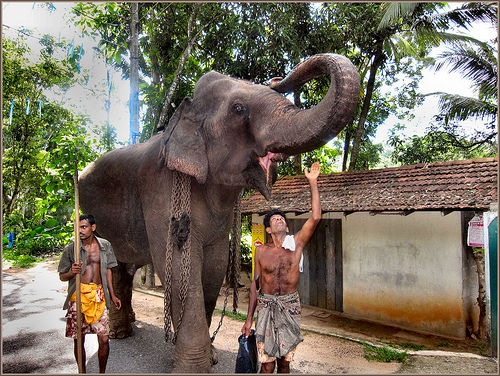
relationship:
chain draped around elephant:
[157, 171, 194, 346] [77, 52, 361, 374]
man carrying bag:
[240, 161, 330, 376] [234, 329, 259, 372]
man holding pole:
[53, 215, 124, 375] [66, 161, 86, 376]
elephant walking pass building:
[77, 52, 361, 374] [230, 159, 498, 356]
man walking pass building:
[256, 161, 316, 371] [241, 167, 496, 344]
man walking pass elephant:
[53, 215, 124, 375] [77, 52, 361, 374]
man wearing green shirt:
[53, 215, 124, 375] [58, 234, 118, 309]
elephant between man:
[77, 52, 361, 374] [240, 161, 330, 376]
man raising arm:
[240, 161, 330, 376] [297, 159, 324, 246]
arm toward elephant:
[297, 159, 324, 246] [77, 52, 361, 374]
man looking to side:
[44, 190, 108, 363] [56, 239, 96, 350]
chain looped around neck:
[157, 171, 194, 346] [166, 103, 238, 222]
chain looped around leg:
[157, 171, 194, 346] [164, 245, 227, 362]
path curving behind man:
[1, 249, 498, 372] [53, 215, 124, 375]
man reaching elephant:
[240, 161, 330, 376] [77, 52, 361, 374]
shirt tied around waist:
[248, 287, 303, 362] [255, 289, 302, 303]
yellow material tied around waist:
[69, 282, 105, 321] [70, 278, 102, 293]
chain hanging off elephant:
[140, 132, 285, 356] [46, 79, 368, 284]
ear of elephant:
[140, 70, 240, 190] [12, 12, 372, 369]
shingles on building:
[245, 158, 495, 219] [241, 167, 496, 344]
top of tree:
[96, 1, 286, 58] [413, 2, 499, 173]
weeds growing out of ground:
[336, 323, 430, 371] [0, 270, 439, 359]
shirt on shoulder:
[283, 233, 308, 275] [284, 233, 298, 246]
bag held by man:
[232, 321, 258, 373] [240, 161, 330, 376]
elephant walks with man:
[77, 52, 361, 374] [240, 161, 330, 376]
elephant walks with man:
[77, 52, 361, 374] [53, 215, 124, 375]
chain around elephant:
[157, 171, 194, 346] [77, 52, 361, 374]